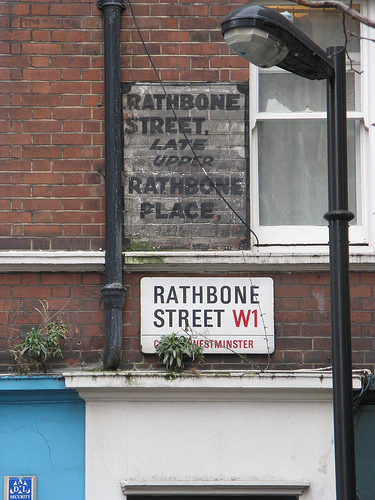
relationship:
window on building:
[247, 2, 369, 247] [1, 0, 374, 499]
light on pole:
[215, 10, 299, 75] [314, 35, 374, 497]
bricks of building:
[18, 0, 86, 248] [1, 0, 374, 499]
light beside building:
[220, 0, 331, 85] [1, 0, 374, 499]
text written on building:
[122, 86, 245, 223] [1, 0, 373, 375]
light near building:
[220, 0, 331, 85] [1, 0, 373, 375]